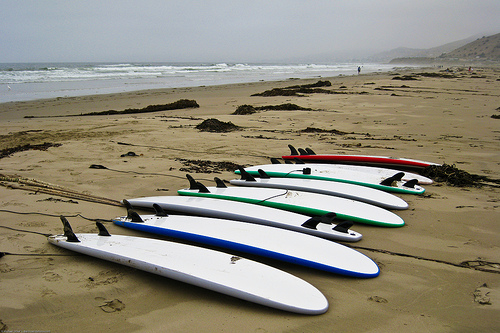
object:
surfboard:
[284, 143, 452, 168]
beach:
[1, 68, 499, 330]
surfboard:
[236, 154, 425, 197]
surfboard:
[232, 167, 409, 215]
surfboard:
[179, 173, 404, 235]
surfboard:
[121, 188, 363, 248]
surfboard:
[115, 200, 381, 288]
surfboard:
[48, 216, 329, 318]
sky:
[0, 2, 499, 61]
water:
[0, 62, 422, 103]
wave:
[0, 61, 275, 78]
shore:
[1, 66, 445, 132]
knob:
[95, 219, 110, 236]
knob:
[63, 226, 80, 242]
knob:
[58, 215, 69, 227]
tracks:
[0, 182, 118, 206]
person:
[355, 66, 361, 74]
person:
[466, 66, 473, 72]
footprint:
[45, 270, 61, 283]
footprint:
[24, 244, 44, 255]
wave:
[211, 62, 349, 73]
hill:
[368, 31, 499, 68]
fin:
[305, 147, 316, 155]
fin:
[297, 148, 306, 155]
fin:
[287, 143, 299, 156]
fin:
[126, 209, 142, 223]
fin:
[152, 203, 168, 217]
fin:
[123, 199, 132, 215]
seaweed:
[194, 117, 239, 133]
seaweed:
[231, 104, 256, 116]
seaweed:
[21, 99, 200, 117]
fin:
[195, 180, 209, 193]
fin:
[214, 176, 225, 188]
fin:
[185, 174, 197, 190]